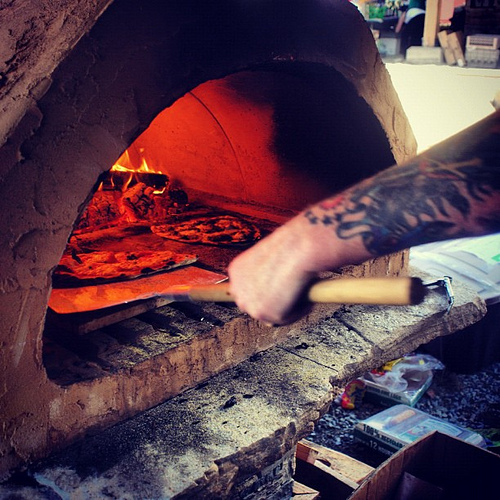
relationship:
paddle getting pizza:
[47, 267, 422, 340] [56, 249, 198, 286]